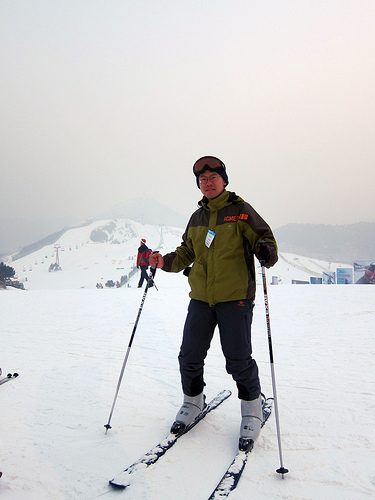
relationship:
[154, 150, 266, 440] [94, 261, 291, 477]
man holding poles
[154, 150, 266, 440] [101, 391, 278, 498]
man standing on skis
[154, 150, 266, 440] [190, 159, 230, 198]
man has head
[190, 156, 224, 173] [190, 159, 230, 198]
goggles on top of head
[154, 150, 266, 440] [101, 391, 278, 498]
man wears skis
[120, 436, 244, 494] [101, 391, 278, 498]
snow on top of skis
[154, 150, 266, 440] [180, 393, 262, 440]
man wearing boots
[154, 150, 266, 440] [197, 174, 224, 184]
man wearing glasses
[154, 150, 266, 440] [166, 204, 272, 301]
man wearing jacket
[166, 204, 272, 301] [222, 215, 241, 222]
jacket says acme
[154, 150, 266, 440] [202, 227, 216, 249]
man wearing tag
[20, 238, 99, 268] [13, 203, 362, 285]
lift in distance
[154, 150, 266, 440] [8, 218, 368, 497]
man skiing on mountain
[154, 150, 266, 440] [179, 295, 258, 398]
man wearing pants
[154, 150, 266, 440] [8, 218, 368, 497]
man on top of mountain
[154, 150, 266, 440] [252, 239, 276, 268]
man with gloves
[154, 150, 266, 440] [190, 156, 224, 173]
man with goggles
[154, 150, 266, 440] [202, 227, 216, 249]
man with tag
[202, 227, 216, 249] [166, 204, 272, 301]
tag on front of jacket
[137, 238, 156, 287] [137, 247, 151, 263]
person wearing jacket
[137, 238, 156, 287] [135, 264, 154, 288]
person wearing pants